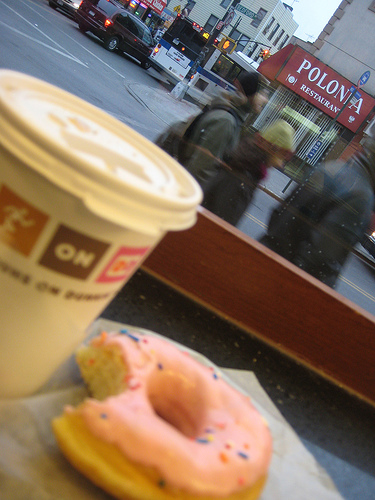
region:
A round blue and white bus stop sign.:
[355, 70, 373, 88]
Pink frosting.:
[86, 333, 274, 487]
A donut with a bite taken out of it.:
[59, 333, 274, 499]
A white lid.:
[0, 68, 200, 235]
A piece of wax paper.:
[0, 316, 345, 499]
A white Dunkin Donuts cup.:
[0, 110, 204, 400]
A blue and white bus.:
[152, 14, 261, 113]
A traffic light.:
[258, 50, 270, 57]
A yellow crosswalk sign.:
[216, 38, 237, 54]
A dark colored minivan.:
[81, 1, 159, 70]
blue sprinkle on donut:
[115, 324, 153, 345]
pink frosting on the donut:
[118, 408, 165, 447]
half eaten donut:
[54, 338, 135, 420]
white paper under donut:
[17, 441, 53, 481]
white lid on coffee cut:
[71, 172, 215, 224]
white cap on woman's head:
[258, 111, 311, 156]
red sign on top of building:
[262, 41, 354, 127]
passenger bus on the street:
[154, 11, 255, 101]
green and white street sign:
[230, 0, 292, 29]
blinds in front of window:
[275, 97, 347, 157]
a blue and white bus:
[158, 34, 263, 93]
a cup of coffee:
[4, 121, 204, 391]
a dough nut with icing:
[78, 328, 286, 494]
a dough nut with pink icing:
[63, 360, 281, 496]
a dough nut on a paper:
[39, 359, 321, 494]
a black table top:
[270, 347, 364, 453]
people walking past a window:
[180, 46, 367, 262]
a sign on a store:
[266, 50, 374, 119]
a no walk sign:
[212, 33, 237, 57]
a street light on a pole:
[253, 43, 270, 62]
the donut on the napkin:
[68, 324, 275, 499]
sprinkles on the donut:
[109, 327, 200, 371]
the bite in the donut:
[78, 344, 126, 425]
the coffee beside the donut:
[0, 66, 196, 389]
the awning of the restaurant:
[261, 37, 372, 133]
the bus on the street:
[162, 11, 255, 103]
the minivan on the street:
[69, 2, 153, 63]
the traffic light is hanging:
[254, 39, 273, 61]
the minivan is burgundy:
[78, 2, 150, 71]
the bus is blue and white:
[161, 11, 250, 114]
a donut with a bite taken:
[60, 326, 281, 496]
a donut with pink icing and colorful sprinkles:
[134, 348, 266, 493]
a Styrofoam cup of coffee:
[4, 102, 195, 369]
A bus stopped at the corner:
[150, 13, 274, 103]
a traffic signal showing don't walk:
[211, 28, 232, 58]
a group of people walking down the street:
[197, 70, 366, 272]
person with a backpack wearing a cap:
[157, 66, 264, 171]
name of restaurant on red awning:
[275, 42, 366, 130]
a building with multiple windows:
[221, 3, 292, 59]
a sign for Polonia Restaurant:
[278, 45, 373, 134]